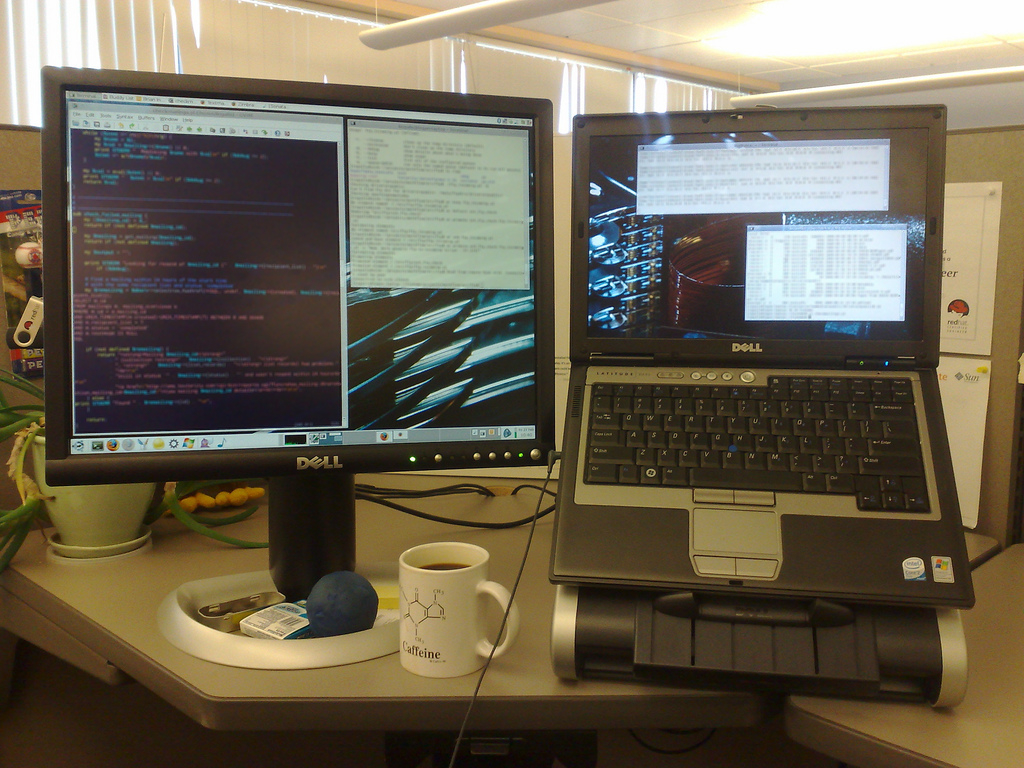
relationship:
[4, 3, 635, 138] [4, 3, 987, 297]
curtain hanging in background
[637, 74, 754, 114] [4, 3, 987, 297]
curtain hanging in background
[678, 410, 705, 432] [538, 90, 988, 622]
key on keyboard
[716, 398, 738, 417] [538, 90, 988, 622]
key on keyboard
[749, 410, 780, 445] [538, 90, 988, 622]
key on keyboard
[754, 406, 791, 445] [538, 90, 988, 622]
key on keyboard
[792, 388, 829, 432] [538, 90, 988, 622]
key on keyboard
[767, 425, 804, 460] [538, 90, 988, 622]
key on keyboard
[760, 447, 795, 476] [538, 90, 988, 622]
key on keyboard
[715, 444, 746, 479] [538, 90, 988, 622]
key on keyboard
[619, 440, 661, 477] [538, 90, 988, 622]
key on keyboard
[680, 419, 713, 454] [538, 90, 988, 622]
key on keyboard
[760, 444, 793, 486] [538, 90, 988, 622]
key on keyboard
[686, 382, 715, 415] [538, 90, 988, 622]
key on keyboard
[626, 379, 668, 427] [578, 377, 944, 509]
key on keyboard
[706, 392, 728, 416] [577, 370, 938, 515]
key on keyboard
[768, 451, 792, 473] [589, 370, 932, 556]
key on computer keyboard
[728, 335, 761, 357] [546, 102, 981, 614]
letters on computer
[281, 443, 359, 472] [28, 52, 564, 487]
logo on monitor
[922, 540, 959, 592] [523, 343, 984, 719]
sticker on laptop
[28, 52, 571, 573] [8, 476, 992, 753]
screen on desk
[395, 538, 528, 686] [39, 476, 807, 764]
coffee cup on desk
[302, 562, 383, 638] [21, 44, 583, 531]
ball under screen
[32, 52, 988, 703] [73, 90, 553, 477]
computer has monitor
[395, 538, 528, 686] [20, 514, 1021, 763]
coffee cup on desk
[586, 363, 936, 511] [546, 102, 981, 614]
keys on computer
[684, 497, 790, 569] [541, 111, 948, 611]
track pad on laptop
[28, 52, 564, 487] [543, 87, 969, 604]
monitor for computer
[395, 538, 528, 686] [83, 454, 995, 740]
coffee cup on desk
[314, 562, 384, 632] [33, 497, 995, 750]
ball on desk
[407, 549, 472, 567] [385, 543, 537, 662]
coffee in mug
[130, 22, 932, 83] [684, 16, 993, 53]
ceiling with light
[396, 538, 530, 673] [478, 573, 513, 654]
coffee cup with handle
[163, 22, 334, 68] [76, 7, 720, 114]
blinds on windows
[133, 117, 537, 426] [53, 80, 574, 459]
image on computer monitor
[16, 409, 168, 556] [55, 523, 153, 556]
planter on base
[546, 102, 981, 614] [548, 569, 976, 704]
computer on stand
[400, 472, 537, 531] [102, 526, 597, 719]
wires above tabletop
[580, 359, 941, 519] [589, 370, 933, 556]
buttons of computer keyboard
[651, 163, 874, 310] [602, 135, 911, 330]
image on screen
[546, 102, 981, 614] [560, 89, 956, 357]
computer with lid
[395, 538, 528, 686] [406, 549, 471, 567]
coffee cup with coffee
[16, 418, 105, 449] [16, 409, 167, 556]
plant in planter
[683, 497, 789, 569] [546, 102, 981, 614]
track pad on computer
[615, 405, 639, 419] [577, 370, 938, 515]
key on keyboard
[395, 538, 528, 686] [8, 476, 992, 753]
coffee cup on desk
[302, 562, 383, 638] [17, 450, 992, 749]
ball on desk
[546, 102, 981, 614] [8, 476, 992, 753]
computer on desk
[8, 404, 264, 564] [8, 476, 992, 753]
flower on desk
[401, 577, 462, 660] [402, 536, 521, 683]
design on cup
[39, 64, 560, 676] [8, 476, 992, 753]
monitor on desk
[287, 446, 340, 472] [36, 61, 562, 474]
letters on screen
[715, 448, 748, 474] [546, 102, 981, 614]
key on computer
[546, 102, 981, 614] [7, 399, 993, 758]
computer on desk